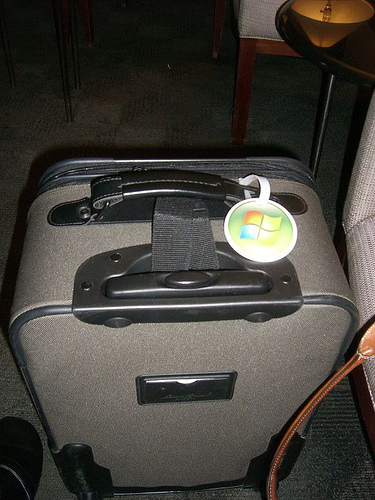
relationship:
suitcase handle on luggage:
[87, 170, 259, 212] [6, 139, 359, 499]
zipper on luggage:
[42, 160, 286, 174] [6, 139, 359, 499]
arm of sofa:
[337, 93, 373, 227] [333, 87, 373, 421]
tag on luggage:
[227, 189, 296, 264] [6, 139, 359, 499]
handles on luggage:
[92, 158, 278, 314] [6, 139, 359, 499]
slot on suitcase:
[124, 367, 254, 405] [8, 156, 361, 500]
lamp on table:
[286, 8, 363, 57] [273, 2, 363, 83]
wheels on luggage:
[71, 457, 304, 497] [35, 138, 345, 457]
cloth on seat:
[344, 228, 363, 257] [346, 121, 362, 264]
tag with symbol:
[224, 197, 298, 263] [241, 201, 281, 250]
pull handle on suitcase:
[104, 270, 272, 297] [11, 109, 341, 463]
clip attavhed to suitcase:
[228, 164, 281, 207] [30, 129, 343, 404]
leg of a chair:
[230, 59, 267, 143] [230, 0, 277, 147]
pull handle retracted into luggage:
[104, 270, 268, 295] [6, 139, 359, 499]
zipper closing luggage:
[42, 160, 286, 174] [6, 139, 359, 499]